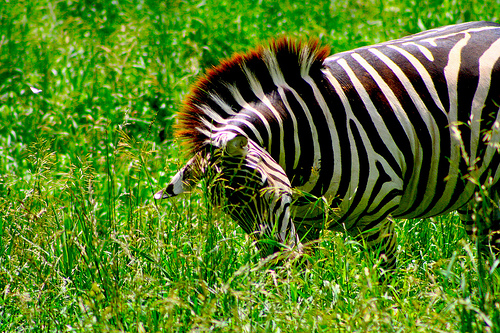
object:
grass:
[0, 0, 493, 332]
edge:
[162, 154, 190, 200]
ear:
[148, 151, 205, 202]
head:
[153, 131, 309, 270]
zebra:
[148, 19, 500, 273]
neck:
[225, 77, 319, 187]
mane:
[168, 31, 334, 147]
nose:
[244, 224, 297, 253]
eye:
[258, 176, 272, 192]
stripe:
[323, 87, 354, 196]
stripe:
[453, 28, 484, 220]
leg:
[356, 218, 399, 291]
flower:
[157, 99, 167, 113]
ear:
[223, 129, 252, 158]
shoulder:
[331, 132, 405, 232]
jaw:
[265, 230, 302, 259]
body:
[301, 19, 498, 286]